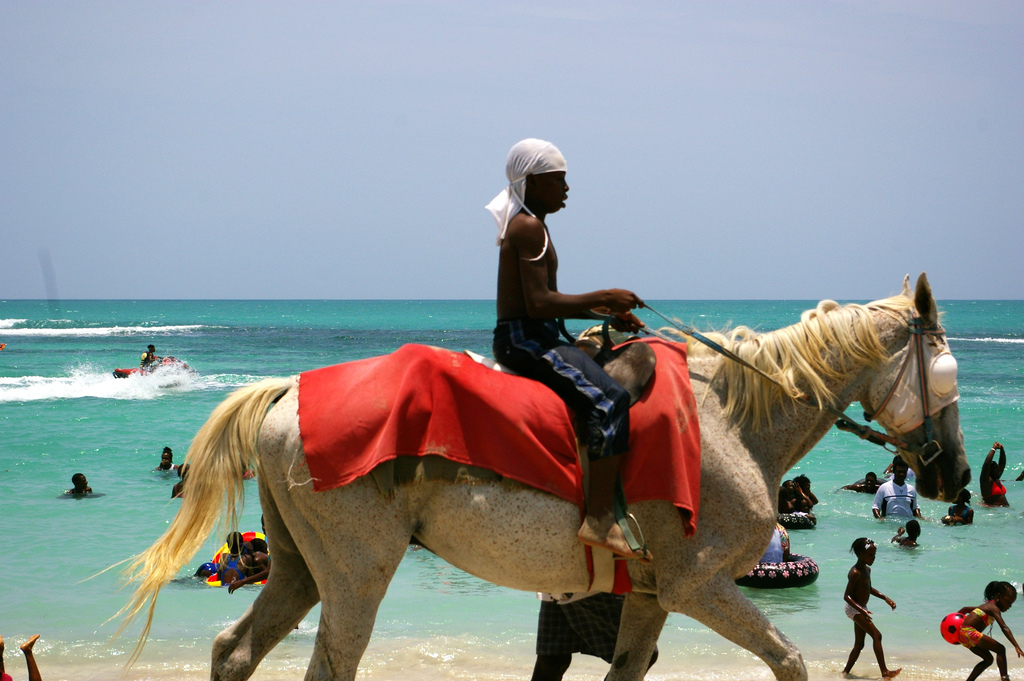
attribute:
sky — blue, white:
[8, 4, 1021, 317]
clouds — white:
[57, 39, 375, 243]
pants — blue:
[524, 324, 630, 502]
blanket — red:
[277, 324, 726, 549]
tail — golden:
[101, 364, 299, 677]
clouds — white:
[83, 119, 150, 180]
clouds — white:
[626, 77, 729, 180]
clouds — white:
[375, 5, 494, 73]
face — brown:
[865, 284, 976, 503]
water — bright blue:
[3, 296, 1021, 672]